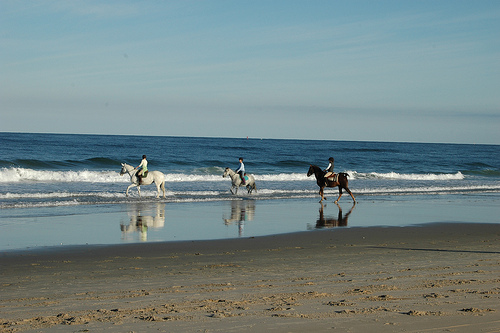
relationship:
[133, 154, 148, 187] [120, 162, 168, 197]
person on horse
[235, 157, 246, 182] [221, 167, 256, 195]
person on horse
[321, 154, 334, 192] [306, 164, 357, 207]
person on horse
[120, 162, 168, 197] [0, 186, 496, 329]
horse on beach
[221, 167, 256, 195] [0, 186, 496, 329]
horse on beach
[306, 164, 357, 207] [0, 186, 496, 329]
horse on beach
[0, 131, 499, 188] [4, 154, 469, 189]
ocean has waves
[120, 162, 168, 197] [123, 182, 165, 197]
horse has legs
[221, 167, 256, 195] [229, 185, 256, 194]
horse has legs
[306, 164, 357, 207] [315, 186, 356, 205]
horse has legs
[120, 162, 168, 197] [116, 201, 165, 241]
horse has reflection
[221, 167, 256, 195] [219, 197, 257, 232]
horse has reflection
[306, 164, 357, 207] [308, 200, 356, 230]
horse has reflection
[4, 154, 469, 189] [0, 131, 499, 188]
waves on ocean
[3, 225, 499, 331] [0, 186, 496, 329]
sand on beach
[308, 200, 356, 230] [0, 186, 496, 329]
reflection on beach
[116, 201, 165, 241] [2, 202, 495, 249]
reflection in water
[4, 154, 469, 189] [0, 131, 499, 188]
waves in water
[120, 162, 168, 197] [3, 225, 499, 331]
horse on sand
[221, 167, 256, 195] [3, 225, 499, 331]
horse on sand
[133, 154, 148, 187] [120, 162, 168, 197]
person rides horse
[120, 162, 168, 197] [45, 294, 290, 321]
horse has footprints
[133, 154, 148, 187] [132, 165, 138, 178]
person holds reins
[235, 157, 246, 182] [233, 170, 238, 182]
person holds reins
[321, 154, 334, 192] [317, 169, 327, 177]
person holds reins